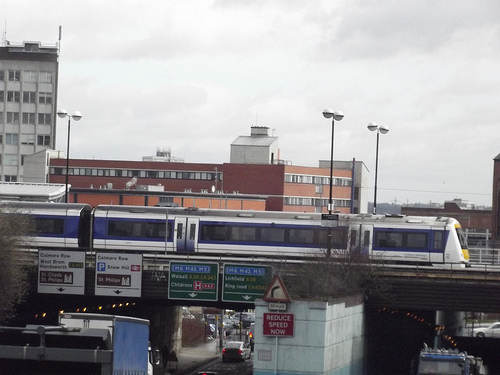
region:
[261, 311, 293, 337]
"Reduce Speed Now" red street sign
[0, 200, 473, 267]
Blue and white passenger train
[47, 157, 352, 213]
Large red brick building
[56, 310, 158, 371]
Blue and white moving van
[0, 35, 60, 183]
Tall white building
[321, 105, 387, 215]
Street light posts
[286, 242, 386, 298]
Dead trees with no foliage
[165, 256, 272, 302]
Green street signs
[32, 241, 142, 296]
White street signs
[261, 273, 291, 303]
Right curve sign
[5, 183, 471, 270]
the train is at the station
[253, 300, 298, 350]
the sign says reduce speed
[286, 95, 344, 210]
the lights are off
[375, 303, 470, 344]
the lights in the tunnel are on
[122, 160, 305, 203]
the building is brick red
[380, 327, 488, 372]
the truck is coming out of the tunnel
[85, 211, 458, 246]
the side of the train is blue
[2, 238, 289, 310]
there are 4 signs above the traffic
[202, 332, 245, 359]
the cars brake lights are on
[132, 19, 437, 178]
the sky is very cloudy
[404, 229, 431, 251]
the window of a train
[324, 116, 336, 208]
a black light post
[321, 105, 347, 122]
a pair of street lights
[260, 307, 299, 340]
a red sign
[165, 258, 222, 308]
a green traffic sign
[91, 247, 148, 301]
a white traffic sign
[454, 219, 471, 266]
the yellow front of a train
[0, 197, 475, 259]
a white and blue train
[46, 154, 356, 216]
a red brick building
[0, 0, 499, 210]
a cloudy gray sky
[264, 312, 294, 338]
red "Reduce Speed Now" sign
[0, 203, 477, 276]
a white and blue elevated commuter train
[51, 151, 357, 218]
a brick building in the background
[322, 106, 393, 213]
tall light posts in the background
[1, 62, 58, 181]
a tall concrete highrise building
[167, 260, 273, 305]
2 green directional street signs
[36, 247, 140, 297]
two large white street signs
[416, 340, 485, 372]
a large truck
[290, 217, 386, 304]
a bush without any leaves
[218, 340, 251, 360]
a silver car with red tail lights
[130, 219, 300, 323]
two green highway signs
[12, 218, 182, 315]
two white highway signs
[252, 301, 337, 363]
this sign is red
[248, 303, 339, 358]
the text is white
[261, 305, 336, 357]
sign says reduce speed now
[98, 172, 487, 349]
train going over a freeway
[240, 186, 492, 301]
the train is white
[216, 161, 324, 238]
a red brick building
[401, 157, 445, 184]
the sky is grey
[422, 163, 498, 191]
the sky is overcast